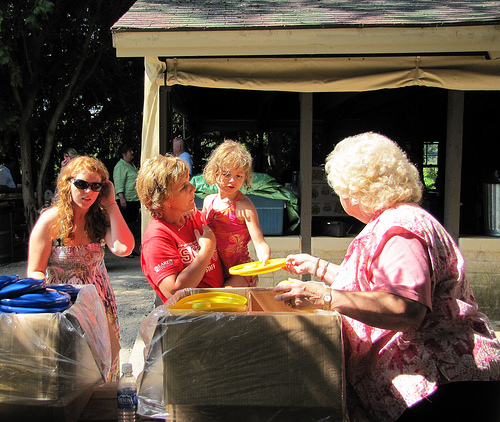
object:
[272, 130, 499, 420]
woman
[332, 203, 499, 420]
shirt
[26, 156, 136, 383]
girl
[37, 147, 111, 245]
red hair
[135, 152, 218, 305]
woman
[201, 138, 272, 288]
child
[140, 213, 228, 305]
shirt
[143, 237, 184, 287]
short sleeves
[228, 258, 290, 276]
frisbee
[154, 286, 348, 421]
box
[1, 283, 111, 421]
box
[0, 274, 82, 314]
frisbees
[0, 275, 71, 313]
blue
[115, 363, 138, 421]
water bottle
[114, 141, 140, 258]
woman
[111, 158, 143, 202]
shirt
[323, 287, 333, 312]
watch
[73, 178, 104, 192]
sunglasses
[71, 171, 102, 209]
face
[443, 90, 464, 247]
post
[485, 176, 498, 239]
trashcan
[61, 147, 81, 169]
woman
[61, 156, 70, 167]
phone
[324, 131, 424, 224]
head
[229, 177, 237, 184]
nose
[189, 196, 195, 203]
mouth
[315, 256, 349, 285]
right arm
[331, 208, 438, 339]
left arm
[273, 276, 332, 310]
left hand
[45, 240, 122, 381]
dress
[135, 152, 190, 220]
hair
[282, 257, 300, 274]
fingers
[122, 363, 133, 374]
cap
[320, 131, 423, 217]
curly white hair